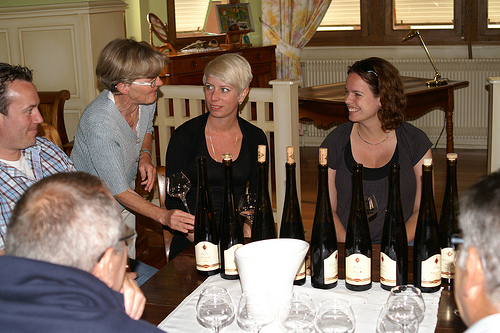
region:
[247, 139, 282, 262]
A bottle of wine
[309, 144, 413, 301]
Three bottles of wine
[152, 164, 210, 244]
Women holding a wine glass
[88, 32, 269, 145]
Two women talking to each other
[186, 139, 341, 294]
5 bottles of wine on a table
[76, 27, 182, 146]
A blond women with glasses looking to her left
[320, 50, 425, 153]
A woman with black hair smiling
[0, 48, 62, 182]
A man with short hair looking to his left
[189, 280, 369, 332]
Several wine glasses on a table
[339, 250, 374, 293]
A label on a wine bottle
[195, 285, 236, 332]
An empty wine glass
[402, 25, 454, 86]
Brass desk lamp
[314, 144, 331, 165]
A wine cork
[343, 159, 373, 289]
An open bittle of wine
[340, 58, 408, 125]
A smiling young woman with sunglasses on her head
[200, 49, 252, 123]
A blond woman with a pixie haircut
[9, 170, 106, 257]
Thinning gray hair of a man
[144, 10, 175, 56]
Small oval personal mirror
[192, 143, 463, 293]
Multiple bottles of wine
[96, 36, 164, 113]
A middle aged woman wearing glasses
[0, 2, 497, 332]
A wine tasting scene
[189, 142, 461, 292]
Bottles of wine are on the table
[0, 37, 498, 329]
People are around the table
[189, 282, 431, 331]
Wine glasses are on the table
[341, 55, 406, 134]
This woman is smiling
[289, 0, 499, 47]
Windows are in the background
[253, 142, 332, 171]
These bottles have corks in them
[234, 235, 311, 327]
A spit bucket is on the table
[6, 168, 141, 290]
This man is wearing glasses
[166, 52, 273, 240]
The lady has a black shirt on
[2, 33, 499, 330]
group of people at restaurant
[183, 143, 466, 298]
nine wine bottles on the table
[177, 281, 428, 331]
five wine glasses on the table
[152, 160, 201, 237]
wine glass in woman's hand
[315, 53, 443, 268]
woman in black shirt smiling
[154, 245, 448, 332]
white tablecloth on the table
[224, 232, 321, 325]
white vase in middle of table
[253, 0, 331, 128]
flower curtains on the window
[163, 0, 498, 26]
white blinds on the windows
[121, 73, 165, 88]
silver glasses on woman's face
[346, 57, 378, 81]
A pair of black sunglasses.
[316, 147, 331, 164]
A wine cork.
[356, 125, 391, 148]
A necklace.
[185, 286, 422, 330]
A row of wine glasses.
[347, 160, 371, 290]
A dark tall bottle with a white and red label.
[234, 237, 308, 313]
A white tall bucket.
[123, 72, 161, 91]
A pair of glasses.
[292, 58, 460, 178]
A wooden desk.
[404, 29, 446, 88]
A shiny desk lamp.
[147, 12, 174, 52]
A round wooden framed mirror.